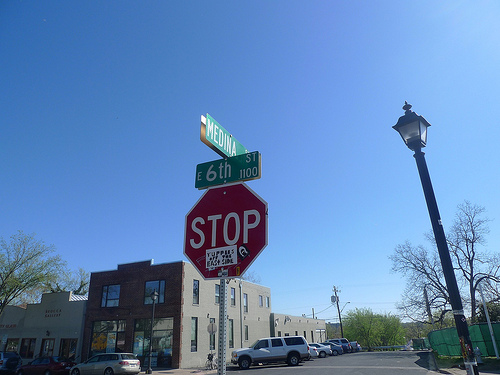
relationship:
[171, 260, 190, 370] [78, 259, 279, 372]
edge of a building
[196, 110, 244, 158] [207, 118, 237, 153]
sign says medina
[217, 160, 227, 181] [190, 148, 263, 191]
letter on sign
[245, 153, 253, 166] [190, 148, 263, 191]
letter on sign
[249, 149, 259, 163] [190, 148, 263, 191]
letter on sign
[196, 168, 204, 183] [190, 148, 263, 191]
letter on sign